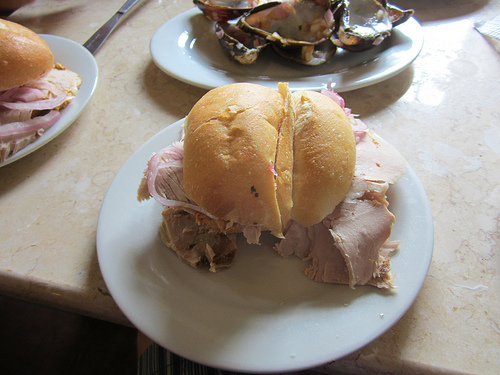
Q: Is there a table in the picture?
A: Yes, there is a table.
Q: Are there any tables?
A: Yes, there is a table.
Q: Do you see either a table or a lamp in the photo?
A: Yes, there is a table.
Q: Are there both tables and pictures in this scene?
A: No, there is a table but no pictures.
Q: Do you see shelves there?
A: No, there are no shelves.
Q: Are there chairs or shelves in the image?
A: No, there are no shelves or chairs.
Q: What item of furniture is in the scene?
A: The piece of furniture is a table.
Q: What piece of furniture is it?
A: The piece of furniture is a table.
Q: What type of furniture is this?
A: This is a table.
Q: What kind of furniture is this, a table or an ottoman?
A: This is a table.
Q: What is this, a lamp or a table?
A: This is a table.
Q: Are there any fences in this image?
A: No, there are no fences.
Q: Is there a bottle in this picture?
A: No, there are no bottles.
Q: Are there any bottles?
A: No, there are no bottles.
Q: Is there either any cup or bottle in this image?
A: No, there are no bottles or cups.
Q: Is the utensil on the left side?
A: Yes, the utensil is on the left of the image.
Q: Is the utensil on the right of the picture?
A: No, the utensil is on the left of the image.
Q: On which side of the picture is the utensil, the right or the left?
A: The utensil is on the left of the image.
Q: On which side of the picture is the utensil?
A: The utensil is on the left of the image.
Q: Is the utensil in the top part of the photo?
A: Yes, the utensil is in the top of the image.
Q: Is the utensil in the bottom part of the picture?
A: No, the utensil is in the top of the image.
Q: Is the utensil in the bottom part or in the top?
A: The utensil is in the top of the image.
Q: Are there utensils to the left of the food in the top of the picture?
A: Yes, there is a utensil to the left of the food.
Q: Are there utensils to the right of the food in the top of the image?
A: No, the utensil is to the left of the food.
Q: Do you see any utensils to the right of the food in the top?
A: No, the utensil is to the left of the food.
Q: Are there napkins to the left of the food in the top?
A: No, there is a utensil to the left of the food.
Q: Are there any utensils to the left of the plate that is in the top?
A: Yes, there is a utensil to the left of the plate.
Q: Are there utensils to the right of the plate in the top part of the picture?
A: No, the utensil is to the left of the plate.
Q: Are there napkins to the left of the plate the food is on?
A: No, there is a utensil to the left of the plate.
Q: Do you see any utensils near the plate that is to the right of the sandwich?
A: Yes, there is a utensil near the plate.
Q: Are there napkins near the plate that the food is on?
A: No, there is a utensil near the plate.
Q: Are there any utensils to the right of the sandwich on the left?
A: Yes, there is a utensil to the right of the sandwich.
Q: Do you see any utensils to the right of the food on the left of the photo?
A: Yes, there is a utensil to the right of the sandwich.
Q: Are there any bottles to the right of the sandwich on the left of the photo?
A: No, there is a utensil to the right of the sandwich.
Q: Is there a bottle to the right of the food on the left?
A: No, there is a utensil to the right of the sandwich.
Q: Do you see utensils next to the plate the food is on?
A: Yes, there is a utensil next to the plate.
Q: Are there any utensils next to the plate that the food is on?
A: Yes, there is a utensil next to the plate.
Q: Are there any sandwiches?
A: Yes, there is a sandwich.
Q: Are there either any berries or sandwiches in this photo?
A: Yes, there is a sandwich.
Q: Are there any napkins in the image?
A: No, there are no napkins.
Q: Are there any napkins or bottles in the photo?
A: No, there are no napkins or bottles.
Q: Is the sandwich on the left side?
A: Yes, the sandwich is on the left of the image.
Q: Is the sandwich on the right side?
A: No, the sandwich is on the left of the image.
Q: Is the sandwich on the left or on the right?
A: The sandwich is on the left of the image.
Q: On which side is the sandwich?
A: The sandwich is on the left of the image.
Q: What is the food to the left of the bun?
A: The food is a sandwich.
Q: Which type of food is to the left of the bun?
A: The food is a sandwich.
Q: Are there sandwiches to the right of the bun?
A: No, the sandwich is to the left of the bun.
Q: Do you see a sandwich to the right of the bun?
A: No, the sandwich is to the left of the bun.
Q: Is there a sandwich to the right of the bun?
A: No, the sandwich is to the left of the bun.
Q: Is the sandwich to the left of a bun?
A: Yes, the sandwich is to the left of a bun.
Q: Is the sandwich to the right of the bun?
A: No, the sandwich is to the left of the bun.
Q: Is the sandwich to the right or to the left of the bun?
A: The sandwich is to the left of the bun.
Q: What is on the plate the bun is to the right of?
A: The sandwich is on the plate.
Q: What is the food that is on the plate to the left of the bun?
A: The food is a sandwich.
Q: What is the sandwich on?
A: The sandwich is on the plate.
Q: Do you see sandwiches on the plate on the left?
A: Yes, there is a sandwich on the plate.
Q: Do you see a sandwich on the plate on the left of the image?
A: Yes, there is a sandwich on the plate.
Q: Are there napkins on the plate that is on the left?
A: No, there is a sandwich on the plate.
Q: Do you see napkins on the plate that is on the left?
A: No, there is a sandwich on the plate.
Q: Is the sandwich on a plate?
A: Yes, the sandwich is on a plate.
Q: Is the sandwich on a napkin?
A: No, the sandwich is on a plate.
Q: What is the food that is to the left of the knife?
A: The food is a sandwich.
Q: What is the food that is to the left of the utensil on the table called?
A: The food is a sandwich.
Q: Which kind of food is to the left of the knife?
A: The food is a sandwich.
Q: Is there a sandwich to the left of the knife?
A: Yes, there is a sandwich to the left of the knife.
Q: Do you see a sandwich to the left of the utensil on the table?
A: Yes, there is a sandwich to the left of the knife.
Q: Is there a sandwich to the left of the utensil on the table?
A: Yes, there is a sandwich to the left of the knife.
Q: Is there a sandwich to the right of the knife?
A: No, the sandwich is to the left of the knife.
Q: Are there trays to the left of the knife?
A: No, there is a sandwich to the left of the knife.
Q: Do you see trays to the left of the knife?
A: No, there is a sandwich to the left of the knife.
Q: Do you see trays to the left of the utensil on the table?
A: No, there is a sandwich to the left of the knife.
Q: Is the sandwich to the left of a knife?
A: Yes, the sandwich is to the left of a knife.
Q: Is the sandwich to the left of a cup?
A: No, the sandwich is to the left of a knife.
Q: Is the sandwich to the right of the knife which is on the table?
A: No, the sandwich is to the left of the knife.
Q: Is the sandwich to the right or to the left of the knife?
A: The sandwich is to the left of the knife.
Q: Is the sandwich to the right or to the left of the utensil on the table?
A: The sandwich is to the left of the knife.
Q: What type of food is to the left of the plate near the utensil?
A: The food is a sandwich.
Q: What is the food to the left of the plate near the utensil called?
A: The food is a sandwich.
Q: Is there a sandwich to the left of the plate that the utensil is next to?
A: Yes, there is a sandwich to the left of the plate.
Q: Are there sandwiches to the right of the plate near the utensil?
A: No, the sandwich is to the left of the plate.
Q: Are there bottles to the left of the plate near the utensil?
A: No, there is a sandwich to the left of the plate.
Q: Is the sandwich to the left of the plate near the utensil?
A: Yes, the sandwich is to the left of the plate.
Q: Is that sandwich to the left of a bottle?
A: No, the sandwich is to the left of the plate.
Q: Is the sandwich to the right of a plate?
A: No, the sandwich is to the left of a plate.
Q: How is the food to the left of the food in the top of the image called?
A: The food is a sandwich.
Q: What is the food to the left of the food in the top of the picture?
A: The food is a sandwich.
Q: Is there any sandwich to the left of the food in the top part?
A: Yes, there is a sandwich to the left of the food.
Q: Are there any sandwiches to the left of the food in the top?
A: Yes, there is a sandwich to the left of the food.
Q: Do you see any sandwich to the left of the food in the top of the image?
A: Yes, there is a sandwich to the left of the food.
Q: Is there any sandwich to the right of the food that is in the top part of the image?
A: No, the sandwich is to the left of the food.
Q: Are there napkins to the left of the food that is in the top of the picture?
A: No, there is a sandwich to the left of the food.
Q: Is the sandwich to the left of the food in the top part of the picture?
A: Yes, the sandwich is to the left of the food.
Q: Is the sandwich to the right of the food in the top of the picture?
A: No, the sandwich is to the left of the food.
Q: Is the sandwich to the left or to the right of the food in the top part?
A: The sandwich is to the left of the food.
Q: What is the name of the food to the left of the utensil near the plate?
A: The food is a sandwich.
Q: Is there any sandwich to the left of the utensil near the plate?
A: Yes, there is a sandwich to the left of the utensil.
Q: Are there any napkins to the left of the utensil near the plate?
A: No, there is a sandwich to the left of the utensil.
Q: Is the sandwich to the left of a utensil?
A: Yes, the sandwich is to the left of a utensil.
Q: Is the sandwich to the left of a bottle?
A: No, the sandwich is to the left of a utensil.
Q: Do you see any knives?
A: Yes, there is a knife.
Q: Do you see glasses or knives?
A: Yes, there is a knife.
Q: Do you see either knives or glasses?
A: Yes, there is a knife.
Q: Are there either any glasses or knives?
A: Yes, there is a knife.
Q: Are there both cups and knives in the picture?
A: No, there is a knife but no cups.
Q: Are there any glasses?
A: No, there are no glasses.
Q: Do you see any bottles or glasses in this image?
A: No, there are no glasses or bottles.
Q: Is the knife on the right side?
A: No, the knife is on the left of the image.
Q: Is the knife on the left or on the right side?
A: The knife is on the left of the image.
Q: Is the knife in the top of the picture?
A: Yes, the knife is in the top of the image.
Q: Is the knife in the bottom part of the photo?
A: No, the knife is in the top of the image.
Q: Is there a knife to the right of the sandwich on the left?
A: Yes, there is a knife to the right of the sandwich.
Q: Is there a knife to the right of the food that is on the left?
A: Yes, there is a knife to the right of the sandwich.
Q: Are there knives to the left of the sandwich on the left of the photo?
A: No, the knife is to the right of the sandwich.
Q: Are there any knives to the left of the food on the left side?
A: No, the knife is to the right of the sandwich.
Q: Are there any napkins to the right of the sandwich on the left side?
A: No, there is a knife to the right of the sandwich.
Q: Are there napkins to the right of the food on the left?
A: No, there is a knife to the right of the sandwich.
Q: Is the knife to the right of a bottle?
A: No, the knife is to the right of a sandwich.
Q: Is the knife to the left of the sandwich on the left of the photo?
A: No, the knife is to the right of the sandwich.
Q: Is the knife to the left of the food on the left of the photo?
A: No, the knife is to the right of the sandwich.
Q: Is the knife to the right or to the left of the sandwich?
A: The knife is to the right of the sandwich.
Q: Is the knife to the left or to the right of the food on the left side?
A: The knife is to the right of the sandwich.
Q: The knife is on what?
A: The knife is on the table.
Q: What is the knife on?
A: The knife is on the table.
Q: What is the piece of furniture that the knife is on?
A: The piece of furniture is a table.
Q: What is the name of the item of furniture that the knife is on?
A: The piece of furniture is a table.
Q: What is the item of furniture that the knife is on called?
A: The piece of furniture is a table.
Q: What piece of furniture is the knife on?
A: The knife is on the table.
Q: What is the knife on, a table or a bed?
A: The knife is on a table.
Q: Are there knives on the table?
A: Yes, there is a knife on the table.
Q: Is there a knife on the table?
A: Yes, there is a knife on the table.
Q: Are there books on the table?
A: No, there is a knife on the table.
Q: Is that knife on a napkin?
A: No, the knife is on the table.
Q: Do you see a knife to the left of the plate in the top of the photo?
A: Yes, there is a knife to the left of the plate.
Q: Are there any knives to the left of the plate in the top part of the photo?
A: Yes, there is a knife to the left of the plate.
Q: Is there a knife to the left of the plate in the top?
A: Yes, there is a knife to the left of the plate.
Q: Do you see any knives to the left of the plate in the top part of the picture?
A: Yes, there is a knife to the left of the plate.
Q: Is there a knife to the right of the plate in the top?
A: No, the knife is to the left of the plate.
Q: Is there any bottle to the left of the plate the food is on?
A: No, there is a knife to the left of the plate.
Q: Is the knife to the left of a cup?
A: No, the knife is to the left of the plate.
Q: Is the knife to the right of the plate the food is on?
A: No, the knife is to the left of the plate.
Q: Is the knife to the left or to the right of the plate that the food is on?
A: The knife is to the left of the plate.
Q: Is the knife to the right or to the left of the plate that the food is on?
A: The knife is to the left of the plate.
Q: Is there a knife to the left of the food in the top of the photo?
A: Yes, there is a knife to the left of the food.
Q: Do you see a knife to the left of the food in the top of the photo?
A: Yes, there is a knife to the left of the food.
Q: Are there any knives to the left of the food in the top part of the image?
A: Yes, there is a knife to the left of the food.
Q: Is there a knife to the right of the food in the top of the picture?
A: No, the knife is to the left of the food.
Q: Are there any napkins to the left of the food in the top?
A: No, there is a knife to the left of the food.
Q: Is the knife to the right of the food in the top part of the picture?
A: No, the knife is to the left of the food.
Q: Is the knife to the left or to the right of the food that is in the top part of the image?
A: The knife is to the left of the food.